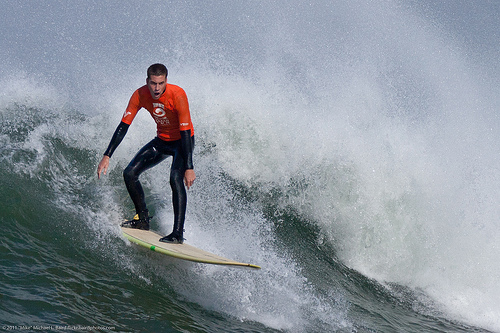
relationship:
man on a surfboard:
[89, 59, 197, 247] [108, 217, 263, 276]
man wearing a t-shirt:
[89, 59, 197, 247] [120, 83, 198, 144]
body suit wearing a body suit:
[89, 59, 197, 247] [97, 77, 203, 236]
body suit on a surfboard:
[89, 59, 197, 247] [108, 217, 263, 276]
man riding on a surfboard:
[89, 59, 197, 247] [108, 217, 263, 276]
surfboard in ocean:
[108, 217, 263, 276] [4, 93, 499, 332]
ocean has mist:
[4, 93, 499, 332] [153, 38, 495, 314]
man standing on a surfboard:
[89, 59, 197, 247] [108, 217, 263, 276]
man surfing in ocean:
[89, 59, 197, 247] [4, 93, 499, 332]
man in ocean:
[89, 59, 197, 247] [4, 93, 499, 332]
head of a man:
[144, 64, 169, 99] [89, 59, 197, 247]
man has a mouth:
[89, 59, 197, 247] [153, 91, 162, 98]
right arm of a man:
[93, 90, 143, 180] [89, 59, 197, 247]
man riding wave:
[89, 59, 197, 247] [9, 92, 335, 258]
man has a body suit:
[89, 59, 197, 247] [97, 77, 203, 236]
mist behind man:
[153, 38, 495, 314] [89, 59, 197, 247]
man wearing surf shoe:
[89, 59, 197, 247] [156, 230, 186, 246]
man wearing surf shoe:
[89, 59, 197, 247] [117, 212, 155, 230]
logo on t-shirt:
[153, 108, 167, 117] [120, 83, 198, 144]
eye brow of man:
[157, 79, 163, 83] [89, 59, 197, 247]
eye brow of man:
[148, 78, 156, 84] [89, 59, 197, 247]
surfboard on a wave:
[108, 217, 263, 276] [9, 92, 335, 258]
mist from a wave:
[153, 38, 495, 314] [9, 92, 335, 258]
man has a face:
[89, 59, 197, 247] [147, 74, 163, 99]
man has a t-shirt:
[89, 59, 197, 247] [120, 83, 198, 144]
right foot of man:
[119, 215, 149, 230] [89, 59, 197, 247]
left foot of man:
[159, 232, 184, 242] [89, 59, 197, 247]